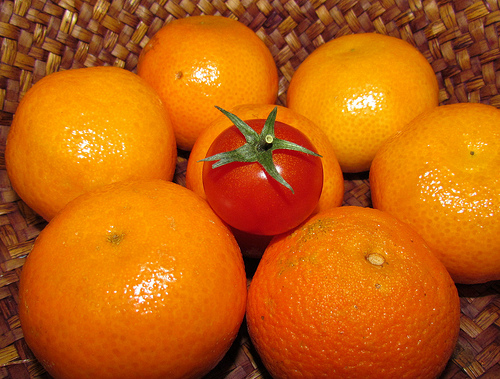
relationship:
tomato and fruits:
[198, 115, 326, 236] [44, 81, 198, 311]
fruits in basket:
[44, 81, 198, 311] [25, 7, 168, 48]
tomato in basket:
[198, 115, 326, 236] [25, 7, 168, 48]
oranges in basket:
[19, 45, 274, 149] [25, 7, 168, 48]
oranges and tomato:
[19, 45, 274, 149] [198, 115, 326, 236]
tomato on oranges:
[198, 115, 326, 236] [19, 45, 274, 149]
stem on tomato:
[241, 126, 292, 168] [198, 115, 326, 236]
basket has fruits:
[25, 7, 168, 48] [44, 81, 198, 311]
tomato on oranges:
[195, 122, 355, 252] [19, 45, 274, 149]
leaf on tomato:
[230, 109, 316, 185] [195, 122, 355, 252]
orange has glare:
[285, 34, 430, 165] [340, 84, 385, 122]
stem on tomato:
[241, 126, 292, 168] [195, 122, 355, 252]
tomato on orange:
[195, 122, 355, 252] [285, 34, 430, 165]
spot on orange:
[293, 115, 323, 146] [285, 34, 430, 165]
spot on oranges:
[293, 115, 323, 146] [19, 45, 274, 149]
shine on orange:
[63, 110, 156, 179] [29, 75, 180, 194]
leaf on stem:
[230, 109, 316, 185] [241, 126, 292, 168]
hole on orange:
[351, 235, 397, 273] [279, 247, 427, 376]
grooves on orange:
[59, 103, 144, 136] [285, 34, 430, 165]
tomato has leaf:
[195, 122, 355, 252] [230, 109, 316, 185]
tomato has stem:
[195, 122, 355, 252] [241, 126, 292, 168]